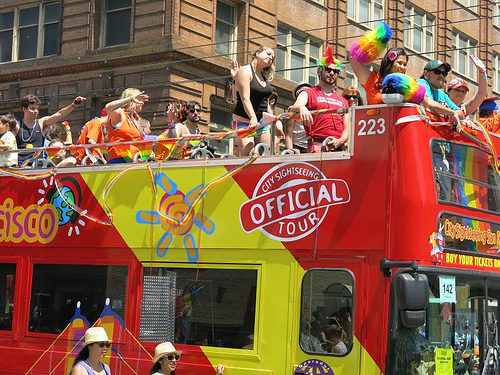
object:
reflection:
[303, 280, 345, 354]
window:
[299, 264, 352, 354]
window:
[140, 262, 256, 351]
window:
[29, 260, 127, 337]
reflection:
[171, 267, 253, 346]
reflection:
[29, 266, 95, 330]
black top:
[230, 64, 274, 120]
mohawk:
[320, 46, 337, 69]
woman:
[64, 321, 121, 373]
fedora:
[78, 321, 110, 347]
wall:
[9, 1, 183, 151]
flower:
[388, 47, 401, 62]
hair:
[376, 48, 398, 72]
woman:
[349, 48, 408, 107]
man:
[176, 100, 201, 153]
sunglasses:
[188, 107, 201, 112]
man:
[294, 54, 345, 151]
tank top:
[236, 62, 271, 118]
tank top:
[18, 116, 45, 159]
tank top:
[73, 360, 109, 372]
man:
[295, 58, 348, 138]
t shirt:
[299, 82, 346, 132]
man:
[16, 92, 61, 179]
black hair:
[17, 90, 39, 105]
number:
[440, 278, 456, 300]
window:
[431, 283, 497, 365]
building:
[0, 0, 165, 77]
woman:
[230, 42, 274, 156]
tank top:
[110, 111, 144, 157]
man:
[416, 54, 468, 111]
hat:
[424, 56, 453, 76]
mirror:
[380, 256, 431, 331]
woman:
[103, 87, 149, 162]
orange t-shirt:
[105, 110, 145, 160]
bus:
[0, 106, 495, 370]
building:
[0, 0, 149, 97]